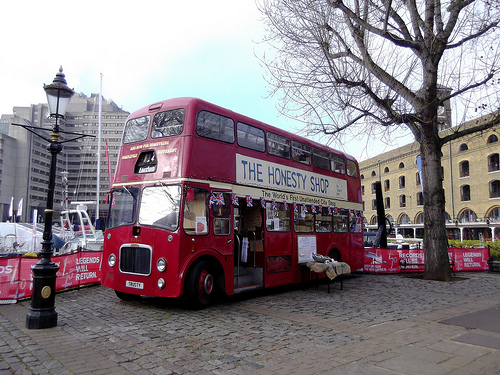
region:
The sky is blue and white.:
[118, 30, 237, 85]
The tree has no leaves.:
[287, 3, 494, 130]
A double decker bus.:
[98, 100, 382, 324]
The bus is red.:
[101, 92, 383, 309]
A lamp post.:
[11, 59, 82, 341]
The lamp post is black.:
[15, 62, 80, 337]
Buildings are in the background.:
[301, 72, 499, 273]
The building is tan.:
[343, 86, 498, 235]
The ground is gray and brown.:
[260, 317, 420, 368]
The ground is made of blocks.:
[271, 317, 411, 373]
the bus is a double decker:
[96, 95, 366, 303]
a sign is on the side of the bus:
[233, 148, 351, 208]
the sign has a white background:
[237, 150, 352, 207]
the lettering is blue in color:
[240, 158, 333, 198]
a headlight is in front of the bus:
[151, 258, 170, 274]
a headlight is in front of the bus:
[106, 253, 116, 268]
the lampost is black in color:
[24, 66, 82, 333]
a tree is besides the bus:
[266, 48, 478, 281]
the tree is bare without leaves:
[258, 50, 497, 285]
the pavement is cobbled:
[4, 256, 495, 373]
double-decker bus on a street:
[91, 90, 385, 307]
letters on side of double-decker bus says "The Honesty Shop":
[220, 141, 364, 213]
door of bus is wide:
[220, 189, 272, 295]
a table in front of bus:
[290, 243, 357, 297]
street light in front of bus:
[18, 62, 99, 333]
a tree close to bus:
[268, 6, 498, 283]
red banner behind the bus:
[0, 243, 108, 300]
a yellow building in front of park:
[366, 113, 498, 226]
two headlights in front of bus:
[99, 242, 171, 293]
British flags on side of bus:
[181, 180, 364, 225]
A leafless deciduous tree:
[285, 0, 498, 278]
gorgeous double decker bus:
[100, 107, 376, 307]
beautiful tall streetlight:
[35, 72, 75, 347]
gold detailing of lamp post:
[40, 285, 55, 297]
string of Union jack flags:
[197, 187, 365, 222]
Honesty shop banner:
[218, 148, 353, 195]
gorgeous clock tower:
[402, 82, 467, 132]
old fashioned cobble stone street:
[78, 330, 369, 367]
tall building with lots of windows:
[3, 90, 123, 207]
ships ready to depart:
[7, 208, 109, 256]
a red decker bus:
[78, 73, 410, 324]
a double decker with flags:
[100, 85, 403, 327]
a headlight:
[88, 241, 173, 279]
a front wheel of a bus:
[180, 250, 227, 317]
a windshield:
[98, 179, 183, 240]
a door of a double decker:
[220, 178, 278, 302]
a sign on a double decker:
[224, 150, 349, 199]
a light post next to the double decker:
[14, 76, 102, 348]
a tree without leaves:
[367, 77, 496, 294]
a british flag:
[204, 187, 230, 207]